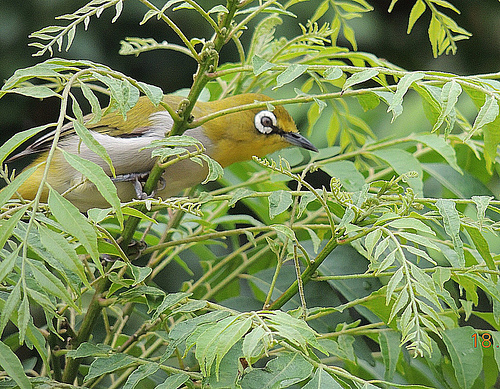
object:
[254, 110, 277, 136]
ring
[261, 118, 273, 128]
eye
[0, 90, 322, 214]
bird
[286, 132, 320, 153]
beak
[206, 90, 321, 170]
head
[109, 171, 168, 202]
talons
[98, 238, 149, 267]
talons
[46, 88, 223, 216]
body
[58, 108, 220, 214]
underside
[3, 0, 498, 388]
plants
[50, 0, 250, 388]
branch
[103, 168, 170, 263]
feet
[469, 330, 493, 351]
18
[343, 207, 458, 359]
leaves